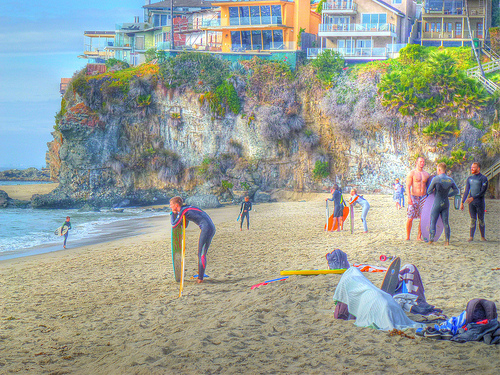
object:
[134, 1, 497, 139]
yellow house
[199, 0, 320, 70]
house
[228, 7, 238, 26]
window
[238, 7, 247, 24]
window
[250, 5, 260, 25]
window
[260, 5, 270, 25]
window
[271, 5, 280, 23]
window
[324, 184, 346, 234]
person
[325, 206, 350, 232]
surfboard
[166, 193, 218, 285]
person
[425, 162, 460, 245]
person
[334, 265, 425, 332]
towel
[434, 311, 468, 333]
towel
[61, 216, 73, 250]
man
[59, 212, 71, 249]
surfer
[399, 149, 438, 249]
man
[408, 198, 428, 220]
trunks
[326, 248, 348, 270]
bag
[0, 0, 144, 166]
sky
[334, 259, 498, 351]
man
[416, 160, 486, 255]
man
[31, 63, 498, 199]
cliff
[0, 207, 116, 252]
water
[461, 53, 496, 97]
blue hat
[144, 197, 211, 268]
man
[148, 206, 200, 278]
surfboard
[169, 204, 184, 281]
surfboard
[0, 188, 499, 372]
beach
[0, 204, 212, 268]
sea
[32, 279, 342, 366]
sand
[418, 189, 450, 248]
board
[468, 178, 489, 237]
wetsuit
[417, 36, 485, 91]
stairs